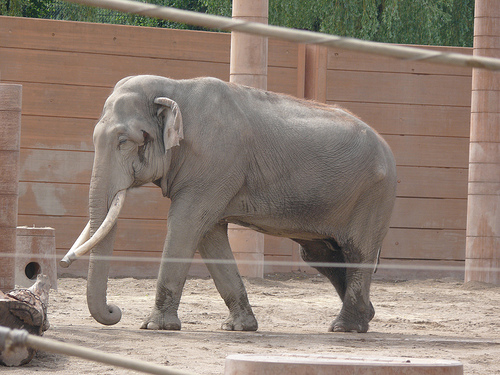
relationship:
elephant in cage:
[60, 62, 411, 357] [0, 1, 499, 374]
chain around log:
[13, 285, 48, 323] [0, 272, 52, 368]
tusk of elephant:
[61, 212, 91, 270] [87, 74, 398, 331]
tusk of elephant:
[72, 191, 129, 265] [87, 74, 398, 331]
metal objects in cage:
[217, 14, 495, 84] [0, 1, 480, 371]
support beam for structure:
[228, 1, 268, 276] [211, 14, 498, 335]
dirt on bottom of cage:
[50, 276, 482, 365] [0, 1, 480, 371]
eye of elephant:
[115, 132, 130, 154] [87, 74, 398, 331]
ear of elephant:
[146, 93, 193, 150] [60, 71, 394, 332]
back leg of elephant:
[328, 236, 383, 331] [60, 71, 394, 332]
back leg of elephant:
[298, 236, 374, 319] [60, 71, 394, 332]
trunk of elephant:
[85, 250, 122, 326] [60, 71, 394, 332]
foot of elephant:
[140, 309, 180, 329] [60, 71, 394, 332]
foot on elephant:
[217, 305, 263, 334] [60, 71, 394, 332]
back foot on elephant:
[327, 306, 368, 333] [60, 71, 394, 332]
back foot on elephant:
[330, 239, 379, 329] [60, 71, 394, 332]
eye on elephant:
[119, 138, 127, 144] [60, 71, 394, 332]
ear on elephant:
[153, 96, 184, 155] [25, 43, 410, 360]